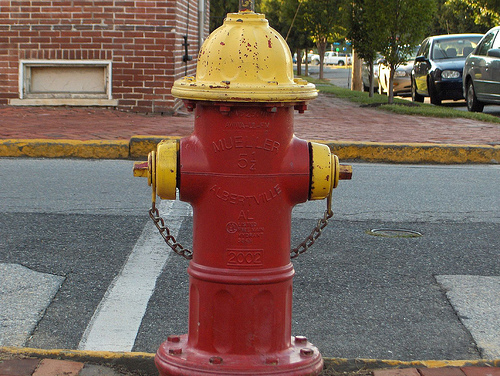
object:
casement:
[7, 59, 120, 107]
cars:
[410, 33, 488, 106]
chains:
[147, 189, 334, 261]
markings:
[74, 185, 193, 351]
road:
[0, 155, 499, 365]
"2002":
[227, 251, 262, 264]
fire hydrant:
[131, 10, 353, 376]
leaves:
[349, 9, 383, 26]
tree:
[346, 0, 435, 105]